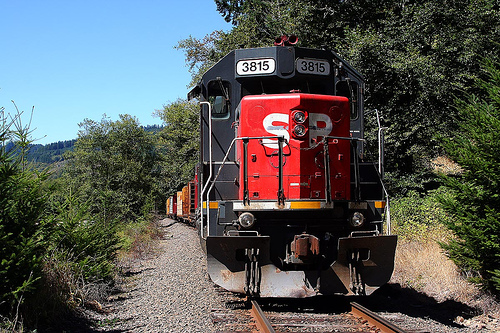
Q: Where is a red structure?
A: On front of train.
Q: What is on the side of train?
A: Green trees.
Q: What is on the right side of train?
A: Trees.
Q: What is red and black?
A: A train engine.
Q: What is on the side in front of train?
A: Bushes.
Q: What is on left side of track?
A: A smaller tree.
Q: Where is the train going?
A: Through the country.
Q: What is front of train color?
A: Red.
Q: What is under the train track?
A: Gravel.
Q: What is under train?
A: Crossties.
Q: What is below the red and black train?
A: Rails of the railroad track.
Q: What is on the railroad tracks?
A: A black and red train engine.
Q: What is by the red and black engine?
A: A large green tree.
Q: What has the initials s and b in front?
A: A red train traveling down tracks.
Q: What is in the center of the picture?
A: A red and black train on tracks.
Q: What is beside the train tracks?
A: A hillside covered in green grass.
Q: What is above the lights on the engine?
A: A metal railing on the front of a train.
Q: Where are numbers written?
A: On train.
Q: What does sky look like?
A: Clear and blue.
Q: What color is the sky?
A: Blue.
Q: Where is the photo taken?
A: By train tracks.